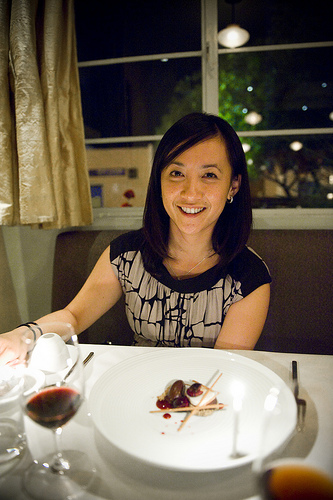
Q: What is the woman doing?
A: She's smiling.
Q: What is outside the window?
A: A green tree.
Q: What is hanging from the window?
A: Light brown curtains.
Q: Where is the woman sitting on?
A: A bench.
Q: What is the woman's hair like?
A: It's black.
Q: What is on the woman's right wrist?
A: Two bangles.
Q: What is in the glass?
A: Red wine.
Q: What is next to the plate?
A: A fork.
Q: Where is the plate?
A: On the table?.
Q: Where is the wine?
A: In the wine glass.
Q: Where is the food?
A: On the plate.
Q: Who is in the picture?
A: A woman.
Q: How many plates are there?
A: One.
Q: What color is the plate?
A: White.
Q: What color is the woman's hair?
A: Black.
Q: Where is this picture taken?
A: At a restaurant.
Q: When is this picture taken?
A: Evening.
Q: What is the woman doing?
A: Dining.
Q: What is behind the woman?
A: Windows.